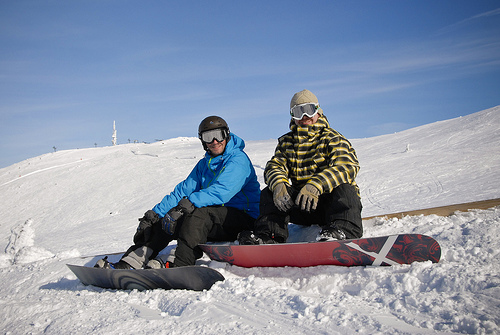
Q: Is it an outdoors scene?
A: Yes, it is outdoors.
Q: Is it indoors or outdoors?
A: It is outdoors.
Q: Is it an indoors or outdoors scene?
A: It is outdoors.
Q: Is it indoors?
A: No, it is outdoors.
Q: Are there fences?
A: No, there are no fences.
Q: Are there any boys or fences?
A: No, there are no fences or boys.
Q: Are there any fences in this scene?
A: No, there are no fences.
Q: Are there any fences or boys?
A: No, there are no fences or boys.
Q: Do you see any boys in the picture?
A: No, there are no boys.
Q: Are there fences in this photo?
A: No, there are no fences.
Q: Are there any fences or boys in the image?
A: No, there are no fences or boys.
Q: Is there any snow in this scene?
A: Yes, there is snow.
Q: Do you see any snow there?
A: Yes, there is snow.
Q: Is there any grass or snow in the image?
A: Yes, there is snow.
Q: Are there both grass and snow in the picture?
A: No, there is snow but no grass.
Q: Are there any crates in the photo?
A: No, there are no crates.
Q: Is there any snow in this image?
A: Yes, there is snow.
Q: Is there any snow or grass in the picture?
A: Yes, there is snow.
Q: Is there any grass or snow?
A: Yes, there is snow.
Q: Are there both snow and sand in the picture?
A: No, there is snow but no sand.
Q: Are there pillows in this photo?
A: No, there are no pillows.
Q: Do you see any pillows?
A: No, there are no pillows.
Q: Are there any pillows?
A: No, there are no pillows.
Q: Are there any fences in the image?
A: No, there are no fences.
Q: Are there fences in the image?
A: No, there are no fences.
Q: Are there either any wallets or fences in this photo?
A: No, there are no fences or wallets.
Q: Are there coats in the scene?
A: Yes, there is a coat.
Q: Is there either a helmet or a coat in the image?
A: Yes, there is a coat.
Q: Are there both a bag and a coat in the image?
A: No, there is a coat but no bags.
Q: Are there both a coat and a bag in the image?
A: No, there is a coat but no bags.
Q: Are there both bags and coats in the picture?
A: No, there is a coat but no bags.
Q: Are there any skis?
A: No, there are no skis.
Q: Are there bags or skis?
A: No, there are no skis or bags.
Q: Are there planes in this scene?
A: No, there are no planes.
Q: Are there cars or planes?
A: No, there are no planes or cars.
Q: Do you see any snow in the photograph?
A: Yes, there is snow.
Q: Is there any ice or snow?
A: Yes, there is snow.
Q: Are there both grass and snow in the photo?
A: No, there is snow but no grass.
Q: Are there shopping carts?
A: No, there are no shopping carts.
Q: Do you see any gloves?
A: Yes, there are gloves.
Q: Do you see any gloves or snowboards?
A: Yes, there are gloves.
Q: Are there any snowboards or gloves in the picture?
A: Yes, there are gloves.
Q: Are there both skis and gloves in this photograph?
A: No, there are gloves but no skis.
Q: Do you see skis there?
A: No, there are no skis.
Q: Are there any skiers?
A: No, there are no skiers.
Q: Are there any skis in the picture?
A: No, there are no skis.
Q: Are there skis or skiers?
A: No, there are no skis or skiers.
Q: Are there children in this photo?
A: No, there are no children.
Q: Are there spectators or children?
A: No, there are no children or spectators.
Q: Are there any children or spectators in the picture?
A: No, there are no children or spectators.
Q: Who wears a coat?
A: The man wears a coat.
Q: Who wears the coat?
A: The man wears a coat.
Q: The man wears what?
A: The man wears a coat.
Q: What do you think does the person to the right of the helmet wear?
A: The man wears a coat.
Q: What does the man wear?
A: The man wears a coat.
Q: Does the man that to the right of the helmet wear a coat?
A: Yes, the man wears a coat.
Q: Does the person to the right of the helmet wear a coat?
A: Yes, the man wears a coat.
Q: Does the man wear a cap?
A: No, the man wears a coat.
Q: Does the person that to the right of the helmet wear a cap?
A: No, the man wears a coat.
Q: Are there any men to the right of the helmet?
A: Yes, there is a man to the right of the helmet.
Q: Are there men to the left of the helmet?
A: No, the man is to the right of the helmet.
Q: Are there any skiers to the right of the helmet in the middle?
A: No, there is a man to the right of the helmet.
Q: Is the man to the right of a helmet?
A: Yes, the man is to the right of a helmet.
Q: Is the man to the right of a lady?
A: No, the man is to the right of a helmet.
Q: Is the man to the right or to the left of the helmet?
A: The man is to the right of the helmet.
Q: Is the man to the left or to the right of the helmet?
A: The man is to the right of the helmet.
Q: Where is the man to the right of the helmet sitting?
A: The man is sitting on the hill.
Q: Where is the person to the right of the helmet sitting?
A: The man is sitting on the hill.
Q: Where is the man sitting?
A: The man is sitting on the hill.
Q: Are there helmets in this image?
A: Yes, there is a helmet.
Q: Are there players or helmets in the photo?
A: Yes, there is a helmet.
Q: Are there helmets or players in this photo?
A: Yes, there is a helmet.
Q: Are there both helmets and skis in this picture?
A: No, there is a helmet but no skis.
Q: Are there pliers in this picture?
A: No, there are no pliers.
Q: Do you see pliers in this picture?
A: No, there are no pliers.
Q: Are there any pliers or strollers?
A: No, there are no pliers or strollers.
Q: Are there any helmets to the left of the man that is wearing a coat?
A: Yes, there is a helmet to the left of the man.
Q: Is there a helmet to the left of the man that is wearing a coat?
A: Yes, there is a helmet to the left of the man.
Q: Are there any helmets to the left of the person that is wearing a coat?
A: Yes, there is a helmet to the left of the man.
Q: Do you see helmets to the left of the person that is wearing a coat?
A: Yes, there is a helmet to the left of the man.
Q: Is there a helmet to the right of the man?
A: No, the helmet is to the left of the man.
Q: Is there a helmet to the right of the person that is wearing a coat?
A: No, the helmet is to the left of the man.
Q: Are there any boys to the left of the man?
A: No, there is a helmet to the left of the man.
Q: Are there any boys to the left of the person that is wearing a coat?
A: No, there is a helmet to the left of the man.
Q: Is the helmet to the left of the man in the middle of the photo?
A: Yes, the helmet is to the left of the man.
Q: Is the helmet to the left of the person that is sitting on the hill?
A: Yes, the helmet is to the left of the man.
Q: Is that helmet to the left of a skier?
A: No, the helmet is to the left of the man.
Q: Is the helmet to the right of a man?
A: No, the helmet is to the left of a man.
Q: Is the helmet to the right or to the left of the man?
A: The helmet is to the left of the man.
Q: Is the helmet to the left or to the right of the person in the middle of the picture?
A: The helmet is to the left of the man.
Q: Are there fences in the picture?
A: No, there are no fences.